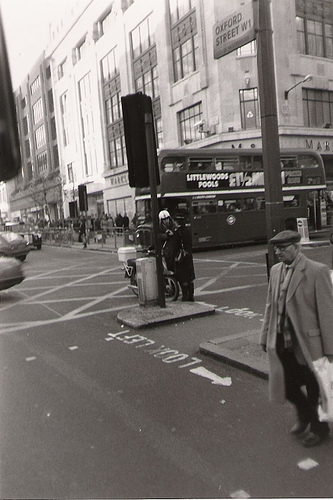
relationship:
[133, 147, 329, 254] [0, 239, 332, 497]
bus in street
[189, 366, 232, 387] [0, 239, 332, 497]
arrow on street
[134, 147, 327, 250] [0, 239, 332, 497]
bus on street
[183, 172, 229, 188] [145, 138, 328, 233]
print on bus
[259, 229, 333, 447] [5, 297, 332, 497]
man on street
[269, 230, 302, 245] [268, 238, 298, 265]
hat on head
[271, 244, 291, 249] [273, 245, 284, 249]
glasses over eyes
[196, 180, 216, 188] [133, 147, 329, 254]
text on bus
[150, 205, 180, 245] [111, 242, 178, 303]
man next to motorcycle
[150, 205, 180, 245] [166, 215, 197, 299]
man talking to woman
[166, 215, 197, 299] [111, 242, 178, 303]
woman next to motorcycle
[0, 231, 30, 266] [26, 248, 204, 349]
cars lying on street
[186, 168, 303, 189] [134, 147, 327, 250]
poster on bus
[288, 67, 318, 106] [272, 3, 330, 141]
traffic lamp on building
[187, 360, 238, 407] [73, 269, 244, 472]
arrow on road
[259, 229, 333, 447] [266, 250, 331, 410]
man with coat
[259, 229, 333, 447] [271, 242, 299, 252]
man with glasses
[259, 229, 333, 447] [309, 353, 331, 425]
man with bag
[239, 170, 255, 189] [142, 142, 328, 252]
1/2 on bus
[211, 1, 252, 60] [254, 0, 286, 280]
sign on pole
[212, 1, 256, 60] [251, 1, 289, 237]
sign on pole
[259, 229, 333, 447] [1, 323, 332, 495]
man crossing street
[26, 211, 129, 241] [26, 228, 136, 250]
people on sidewalk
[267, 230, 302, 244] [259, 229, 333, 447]
hat on man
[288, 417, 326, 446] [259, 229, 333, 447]
shoes on man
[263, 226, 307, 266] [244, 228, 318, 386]
head of man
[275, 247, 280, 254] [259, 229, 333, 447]
nose of man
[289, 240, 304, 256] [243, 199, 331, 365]
ear of man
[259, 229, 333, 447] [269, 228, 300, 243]
man wearing hat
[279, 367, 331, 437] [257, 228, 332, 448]
legs of man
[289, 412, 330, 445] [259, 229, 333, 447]
feet of man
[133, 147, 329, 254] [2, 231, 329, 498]
bus on road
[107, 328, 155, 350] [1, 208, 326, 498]
word painted on street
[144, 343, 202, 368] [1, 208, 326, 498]
word painted on street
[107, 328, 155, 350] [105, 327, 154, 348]
word spelling left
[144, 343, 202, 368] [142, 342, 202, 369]
word spelling look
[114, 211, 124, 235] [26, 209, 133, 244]
person standing in crowd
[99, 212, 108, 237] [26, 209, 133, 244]
person standing in crowd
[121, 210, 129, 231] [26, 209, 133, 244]
person standing in crowd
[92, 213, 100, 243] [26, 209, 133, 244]
person standing in crowd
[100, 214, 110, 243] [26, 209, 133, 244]
person standing in crowd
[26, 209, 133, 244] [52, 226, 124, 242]
crowd standing on sidewalk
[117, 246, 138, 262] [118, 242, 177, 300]
container sitting on top of motorcycle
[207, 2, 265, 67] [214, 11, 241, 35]
signpost reading oxford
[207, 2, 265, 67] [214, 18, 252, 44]
signpost reading street w1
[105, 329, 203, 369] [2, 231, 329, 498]
letter painted on road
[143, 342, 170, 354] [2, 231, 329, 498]
letter painted on road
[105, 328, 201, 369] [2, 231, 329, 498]
look left painted on road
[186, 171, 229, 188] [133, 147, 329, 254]
littlewoods pools painted on bus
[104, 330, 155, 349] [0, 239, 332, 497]
mark painted on street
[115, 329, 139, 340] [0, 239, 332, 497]
mark painted on street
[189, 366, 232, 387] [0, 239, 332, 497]
arrow painted on street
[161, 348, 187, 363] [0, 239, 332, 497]
mark painted on street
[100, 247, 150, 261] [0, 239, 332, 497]
corner rounding street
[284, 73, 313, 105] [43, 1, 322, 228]
light mounted on building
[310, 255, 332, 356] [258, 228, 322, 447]
arms belonging to man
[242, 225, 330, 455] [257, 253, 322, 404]
man wearing coat